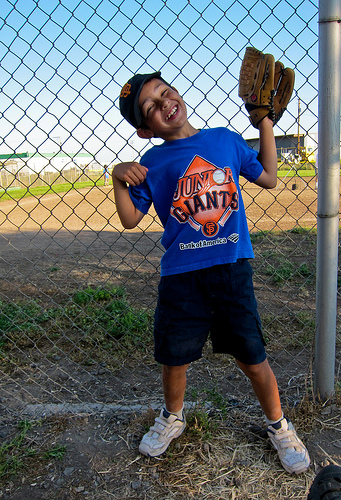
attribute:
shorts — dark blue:
[153, 257, 266, 365]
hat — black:
[219, 34, 271, 107]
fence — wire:
[0, 0, 340, 415]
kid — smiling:
[111, 45, 308, 473]